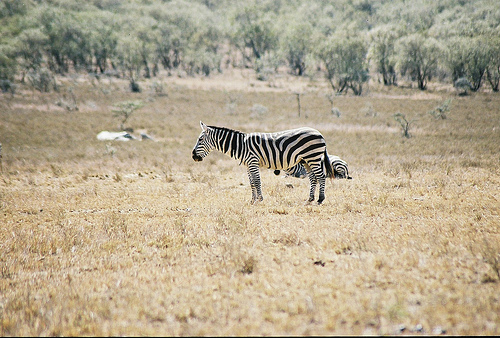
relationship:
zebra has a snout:
[191, 119, 336, 205] [192, 152, 198, 160]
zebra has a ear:
[191, 119, 336, 205] [200, 119, 206, 130]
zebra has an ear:
[191, 119, 336, 205] [200, 119, 206, 130]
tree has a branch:
[316, 31, 369, 95] [249, 37, 261, 59]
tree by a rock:
[316, 31, 369, 95] [97, 130, 150, 143]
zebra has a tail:
[191, 119, 336, 205] [325, 150, 334, 178]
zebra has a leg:
[191, 119, 336, 205] [303, 157, 326, 203]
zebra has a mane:
[191, 119, 336, 205] [209, 126, 246, 136]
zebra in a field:
[191, 119, 336, 205] [0, 72, 500, 338]